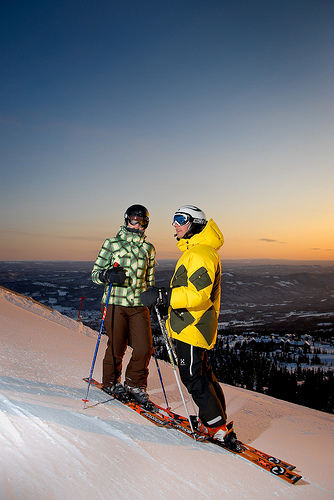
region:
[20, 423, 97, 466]
snow on the ground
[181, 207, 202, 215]
helmet on man's head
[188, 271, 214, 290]
pocket on the jacket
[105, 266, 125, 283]
mitten on man's hand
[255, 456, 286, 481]
part of the ski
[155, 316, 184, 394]
part of the ski pole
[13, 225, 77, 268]
part of the sky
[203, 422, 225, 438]
part of snow shoe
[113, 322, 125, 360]
part of man's brown pants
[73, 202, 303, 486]
skiers on the slope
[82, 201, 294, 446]
skiers on a mountain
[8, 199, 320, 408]
these skiers are skiing at dusk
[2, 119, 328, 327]
a clear sunset sky is behind the skiers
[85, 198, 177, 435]
this skier is wearing a green flannel jacket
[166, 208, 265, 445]
this skier is wearing a yellow and black diamond spotted coat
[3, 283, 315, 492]
there is some artificial light on the slopes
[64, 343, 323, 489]
these skis are orange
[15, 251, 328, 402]
pine trees are spread out across the area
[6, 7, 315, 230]
this sky has no precipitation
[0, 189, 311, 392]
this might be a perfect night for skiing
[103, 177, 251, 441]
Two people skiing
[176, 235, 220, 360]
Wearing yellow checkered outfit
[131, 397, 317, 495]
Skis are orange and red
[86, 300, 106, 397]
Ski pole is long and blue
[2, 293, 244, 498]
Slope of mountain has snow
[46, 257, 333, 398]
Valley below is pretty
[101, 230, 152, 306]
Green and white outfit is puffy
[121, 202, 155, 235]
Wearing black helmet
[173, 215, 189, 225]
Blue and white goggles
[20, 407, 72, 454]
Groove in snow is shallow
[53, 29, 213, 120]
A bright blue sky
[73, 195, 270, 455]
Two people on skis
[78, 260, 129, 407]
A blue and red ski pole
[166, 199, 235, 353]
A yellow and black ski jacket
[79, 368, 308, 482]
Orange, black and white skis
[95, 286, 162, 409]
A person wearing brown ski pants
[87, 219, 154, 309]
A person wearing a plaid jacket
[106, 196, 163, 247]
A person wearing a black helmet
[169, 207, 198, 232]
A person wearing goggles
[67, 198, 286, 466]
Two people standing on snow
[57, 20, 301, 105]
a clear blue sky overhead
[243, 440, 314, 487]
orange and black skis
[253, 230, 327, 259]
an orange sky at sunset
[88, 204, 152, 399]
a woman wearing a plaid coat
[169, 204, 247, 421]
a man wearing a yellow parka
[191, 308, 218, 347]
a gray patch on a yellow parka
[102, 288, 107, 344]
a blue and red ski pole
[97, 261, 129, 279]
black glove on a hand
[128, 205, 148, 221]
a black helmet on a head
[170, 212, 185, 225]
blue snow googles on a face